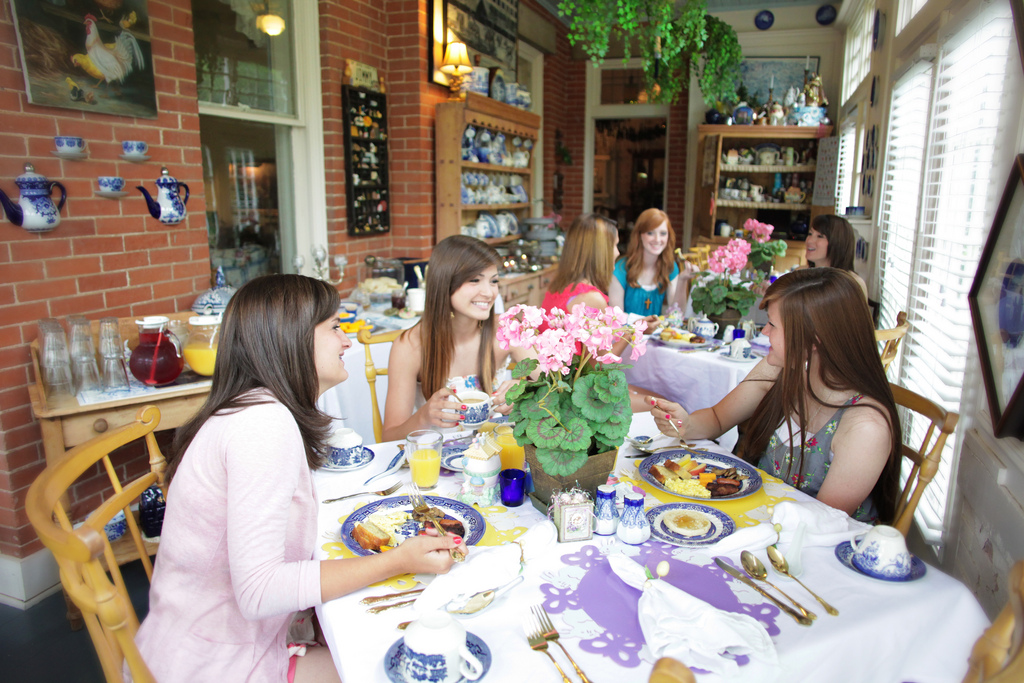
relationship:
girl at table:
[370, 226, 527, 442] [184, 362, 1022, 676]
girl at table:
[637, 260, 913, 526] [248, 392, 982, 680]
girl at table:
[532, 206, 627, 336] [532, 292, 780, 460]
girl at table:
[608, 204, 691, 331] [608, 285, 798, 448]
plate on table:
[633, 434, 761, 512] [248, 392, 982, 680]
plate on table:
[332, 484, 488, 577] [320, 364, 973, 674]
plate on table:
[639, 491, 747, 550] [248, 392, 982, 680]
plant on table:
[481, 291, 652, 525] [250, 367, 1020, 662]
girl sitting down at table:
[788, 210, 866, 287] [598, 291, 867, 456]